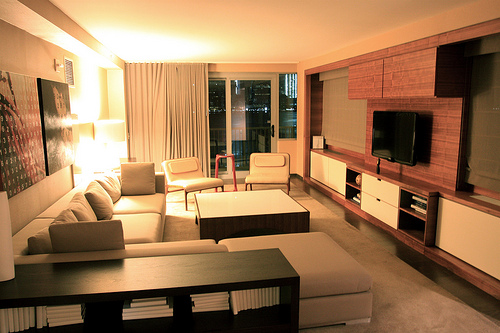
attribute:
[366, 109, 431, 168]
tv — black, off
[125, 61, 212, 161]
curtains — green, white, long, brown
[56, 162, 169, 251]
couch — long, white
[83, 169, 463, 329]
floor — white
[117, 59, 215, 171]
curtain — long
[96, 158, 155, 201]
pillows — white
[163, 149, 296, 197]
chairs — white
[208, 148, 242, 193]
table — red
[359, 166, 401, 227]
drawers — white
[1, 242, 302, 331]
shelf — black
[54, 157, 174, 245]
sofa — white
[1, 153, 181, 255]
sofa — white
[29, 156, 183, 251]
sofa — white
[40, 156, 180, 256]
sofa — white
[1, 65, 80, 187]
painting — large, modern art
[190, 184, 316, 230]
coffee table — square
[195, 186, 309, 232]
ottoman — square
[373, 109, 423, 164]
tv — flat screen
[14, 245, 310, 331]
cabinet — dark brown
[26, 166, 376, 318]
chair — beige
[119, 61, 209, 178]
curtains — beige